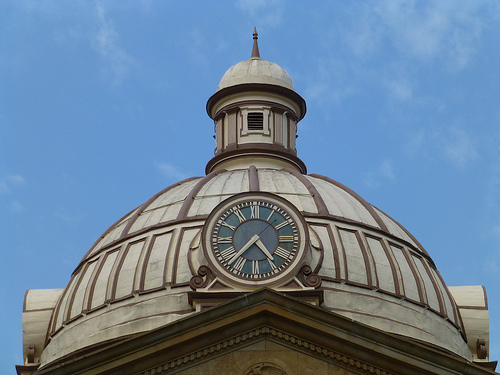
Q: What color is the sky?
A: Light Blue.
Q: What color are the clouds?
A: White.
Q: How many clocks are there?
A: One.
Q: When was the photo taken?
A: Daytime.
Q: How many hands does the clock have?
A: Two.